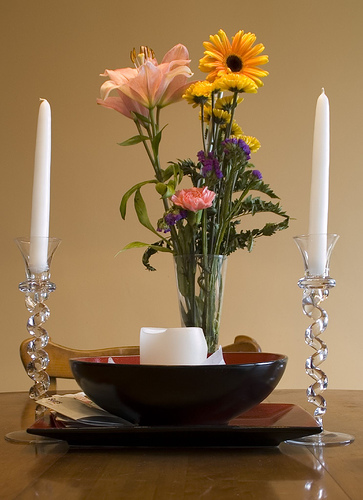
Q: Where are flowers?
A: In the vase.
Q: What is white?
A: Candles.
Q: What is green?
A: Flower stems.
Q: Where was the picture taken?
A: At a table.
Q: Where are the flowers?
A: In a vase.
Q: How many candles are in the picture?
A: 3.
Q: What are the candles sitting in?
A: Candle stick holders.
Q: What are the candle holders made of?
A: Glass.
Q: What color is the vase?
A: Clear.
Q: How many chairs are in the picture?
A: 1.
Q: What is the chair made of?
A: Wood.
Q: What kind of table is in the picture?
A: Dining table.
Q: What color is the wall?
A: Tan.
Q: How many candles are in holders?
A: 2.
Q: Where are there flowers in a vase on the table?
A: Centerpiece.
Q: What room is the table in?
A: Dining area.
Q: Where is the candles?
A: Candle holder.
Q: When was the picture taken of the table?
A: Diner time.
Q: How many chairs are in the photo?
A: 1.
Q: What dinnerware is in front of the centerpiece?
A: Plate and bowl.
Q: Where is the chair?
A: Behind the table.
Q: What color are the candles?
A: White.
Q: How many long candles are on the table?
A: Two.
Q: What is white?
A: Candles.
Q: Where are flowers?
A: In a vase.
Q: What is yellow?
A: Flowers.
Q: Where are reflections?
A: On the table.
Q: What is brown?
A: Table.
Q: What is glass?
A: Vase.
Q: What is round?
A: Bowl.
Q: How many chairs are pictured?
A: One.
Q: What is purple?
A: Flowers.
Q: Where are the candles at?
A: Outside centerpiece.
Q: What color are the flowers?
A: Yellow pink and purple.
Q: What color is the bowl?
A: Black and red.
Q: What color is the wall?
A: Beige.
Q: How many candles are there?
A: 2.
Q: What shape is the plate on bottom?
A: Square.